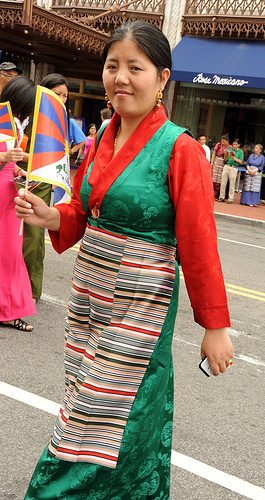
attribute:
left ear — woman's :
[159, 64, 171, 92]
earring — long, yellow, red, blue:
[152, 89, 164, 104]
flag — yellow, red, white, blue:
[35, 85, 73, 195]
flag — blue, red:
[26, 79, 79, 213]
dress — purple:
[235, 147, 263, 183]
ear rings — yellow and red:
[155, 86, 164, 109]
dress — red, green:
[55, 115, 220, 499]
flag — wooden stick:
[12, 59, 87, 227]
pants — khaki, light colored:
[212, 137, 238, 198]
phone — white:
[199, 356, 213, 377]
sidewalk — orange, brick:
[217, 201, 263, 221]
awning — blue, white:
[168, 33, 263, 90]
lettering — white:
[191, 71, 248, 88]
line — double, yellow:
[225, 277, 263, 306]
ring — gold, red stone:
[226, 356, 235, 365]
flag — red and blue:
[0, 101, 20, 144]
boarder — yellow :
[4, 99, 17, 138]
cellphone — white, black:
[198, 353, 213, 377]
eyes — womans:
[105, 62, 141, 71]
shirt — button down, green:
[74, 95, 211, 344]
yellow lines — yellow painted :
[223, 280, 264, 303]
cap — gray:
[0, 59, 43, 81]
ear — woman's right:
[156, 62, 167, 91]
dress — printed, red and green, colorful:
[22, 103, 231, 498]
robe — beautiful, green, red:
[21, 102, 228, 497]